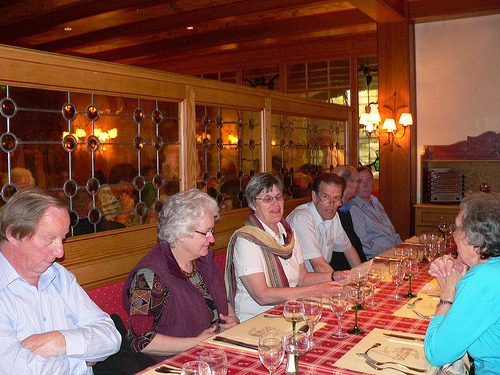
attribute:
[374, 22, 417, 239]
wall — brown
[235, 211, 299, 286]
scarf — striped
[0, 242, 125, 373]
shirt — blue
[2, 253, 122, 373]
shirt — light blue, dress shirt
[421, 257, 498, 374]
shirt — aqua blue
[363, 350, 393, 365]
fork — long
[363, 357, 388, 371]
fork — long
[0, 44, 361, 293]
divider — glass, wooden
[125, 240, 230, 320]
vest — purple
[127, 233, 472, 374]
tablecloth — red, plaid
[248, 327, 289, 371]
glass — tall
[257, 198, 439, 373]
tablecloth — red, pink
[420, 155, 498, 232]
cabinet — wooden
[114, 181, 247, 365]
woman — grey-haired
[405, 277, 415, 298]
stem — green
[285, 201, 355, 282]
shirt — white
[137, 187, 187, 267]
hair — grey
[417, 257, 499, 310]
hands — folded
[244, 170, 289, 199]
hair — salt-and-pepper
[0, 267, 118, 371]
shirt — dress shirt, light blue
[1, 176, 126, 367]
man — light blue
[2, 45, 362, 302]
divider wall — wood, glass